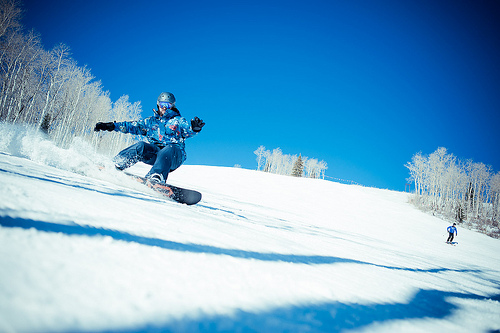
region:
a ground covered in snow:
[110, 172, 289, 311]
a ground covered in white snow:
[190, 226, 327, 328]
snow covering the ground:
[200, 219, 357, 325]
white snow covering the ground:
[289, 225, 413, 325]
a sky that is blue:
[212, 21, 383, 86]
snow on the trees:
[29, 31, 160, 141]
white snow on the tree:
[33, 40, 158, 165]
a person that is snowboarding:
[80, 68, 304, 272]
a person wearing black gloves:
[92, 71, 284, 236]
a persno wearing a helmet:
[110, 58, 185, 189]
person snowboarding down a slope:
[83, 68, 218, 221]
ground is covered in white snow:
[0, 119, 499, 331]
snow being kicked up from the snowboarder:
[1, 74, 217, 216]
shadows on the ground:
[3, 206, 498, 331]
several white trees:
[398, 140, 496, 237]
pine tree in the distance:
[288, 153, 304, 178]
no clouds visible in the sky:
[7, 3, 497, 197]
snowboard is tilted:
[101, 170, 215, 209]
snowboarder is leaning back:
[90, 79, 230, 201]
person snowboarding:
[86, 78, 221, 216]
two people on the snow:
[93, 85, 467, 262]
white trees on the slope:
[396, 138, 498, 236]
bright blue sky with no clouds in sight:
[1, 0, 496, 203]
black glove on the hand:
[87, 117, 117, 135]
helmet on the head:
[158, 89, 178, 108]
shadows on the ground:
[0, 201, 498, 331]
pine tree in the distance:
[286, 152, 308, 177]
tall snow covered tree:
[33, 40, 68, 130]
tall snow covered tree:
[23, 51, 56, 128]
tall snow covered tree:
[0, 39, 24, 119]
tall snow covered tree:
[81, 84, 96, 139]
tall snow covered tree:
[88, 97, 112, 145]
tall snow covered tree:
[402, 148, 424, 203]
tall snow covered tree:
[422, 151, 437, 210]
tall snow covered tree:
[468, 157, 488, 222]